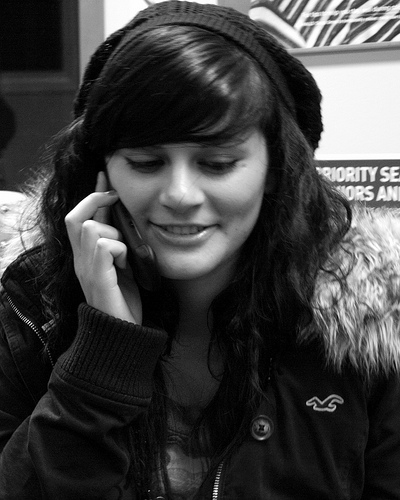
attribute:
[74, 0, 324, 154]
cap — black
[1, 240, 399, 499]
jacket — black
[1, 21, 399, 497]
girl — smiling, talking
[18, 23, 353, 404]
hair — dark, long, black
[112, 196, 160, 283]
phone — cellular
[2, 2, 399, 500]
photograph — black, white